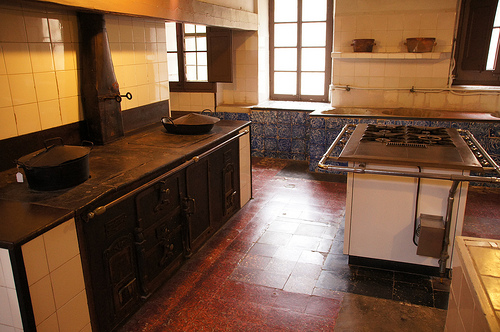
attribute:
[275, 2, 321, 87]
pane — window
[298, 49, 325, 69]
pane — window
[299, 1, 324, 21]
window — Small 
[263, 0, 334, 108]
window — pane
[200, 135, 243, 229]
cabinet — kitchen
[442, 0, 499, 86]
window — pane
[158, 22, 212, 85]
window — pane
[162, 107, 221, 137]
skillet — iron 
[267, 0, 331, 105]
window — pane, Small 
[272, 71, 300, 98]
window — Small 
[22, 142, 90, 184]
skillet — cast iron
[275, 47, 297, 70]
window — Small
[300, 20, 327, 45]
window — Small 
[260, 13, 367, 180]
window — Small 